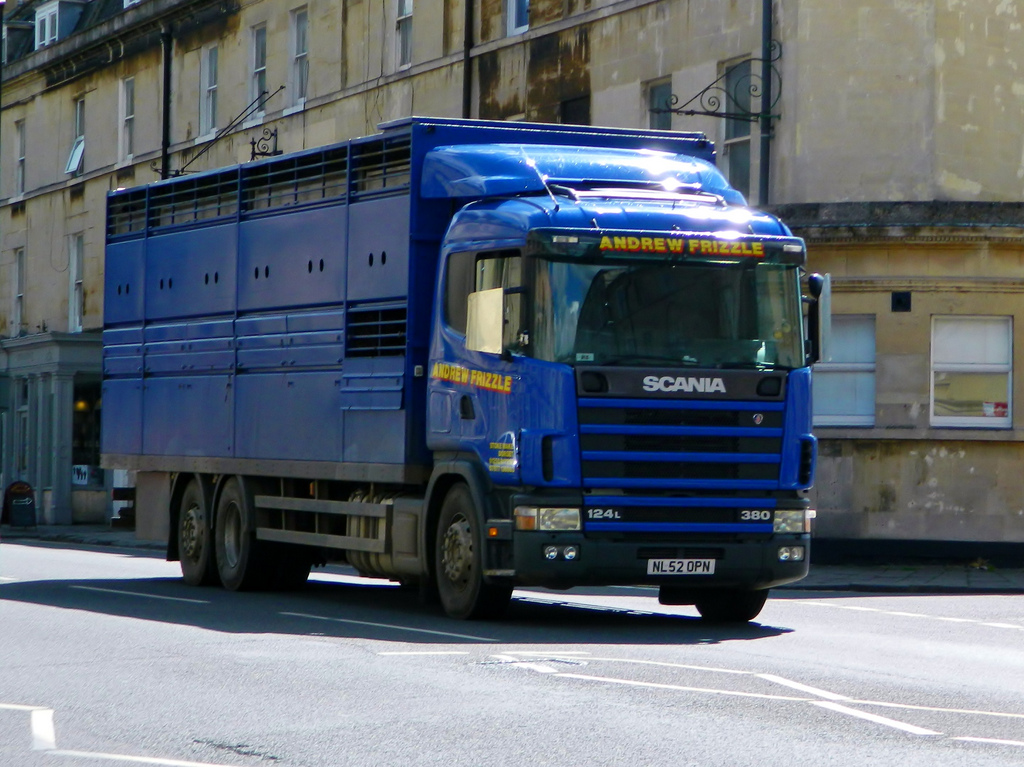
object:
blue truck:
[99, 116, 832, 621]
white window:
[929, 313, 1012, 427]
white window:
[805, 313, 877, 427]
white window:
[247, 20, 266, 119]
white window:
[384, 1, 411, 77]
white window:
[118, 76, 132, 162]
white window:
[65, 92, 89, 179]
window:
[528, 256, 807, 366]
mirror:
[465, 287, 503, 354]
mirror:
[808, 273, 832, 364]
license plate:
[647, 559, 716, 576]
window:
[718, 52, 761, 205]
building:
[0, 0, 1024, 563]